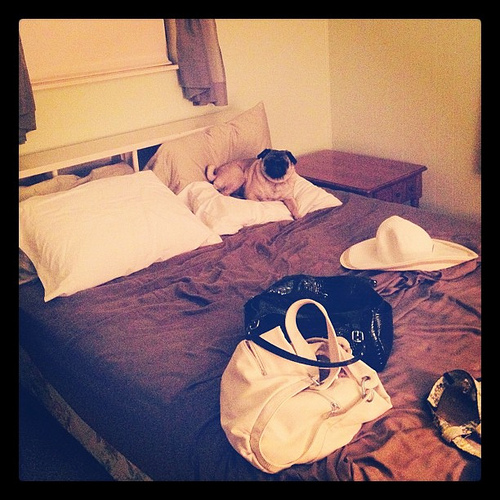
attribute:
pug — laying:
[206, 151, 303, 223]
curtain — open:
[164, 16, 229, 109]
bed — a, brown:
[20, 107, 481, 482]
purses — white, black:
[219, 275, 395, 475]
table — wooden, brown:
[294, 148, 426, 209]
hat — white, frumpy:
[339, 213, 481, 275]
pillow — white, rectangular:
[18, 170, 224, 303]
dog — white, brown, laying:
[206, 148, 305, 222]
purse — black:
[243, 275, 396, 370]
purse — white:
[219, 296, 394, 474]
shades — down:
[20, 20, 178, 92]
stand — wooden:
[294, 148, 426, 209]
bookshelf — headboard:
[18, 106, 244, 234]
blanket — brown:
[18, 185, 482, 481]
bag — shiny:
[245, 271, 396, 374]